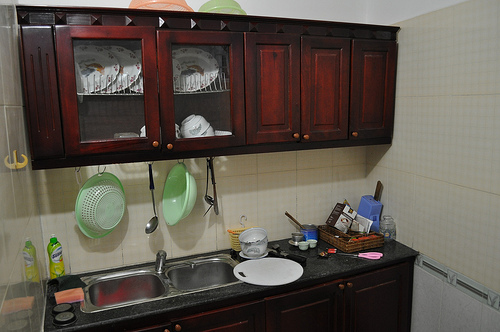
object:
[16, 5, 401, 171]
cabinets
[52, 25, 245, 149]
windows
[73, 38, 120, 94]
dishes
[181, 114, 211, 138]
cups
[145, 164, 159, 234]
ladle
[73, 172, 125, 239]
colanders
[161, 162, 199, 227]
utensils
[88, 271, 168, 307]
sinks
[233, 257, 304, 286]
plate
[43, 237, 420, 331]
counter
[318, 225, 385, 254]
tray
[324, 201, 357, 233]
items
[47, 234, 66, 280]
bottle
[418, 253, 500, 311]
tile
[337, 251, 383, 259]
scissors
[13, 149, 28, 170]
hook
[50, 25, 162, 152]
doors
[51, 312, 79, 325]
stopper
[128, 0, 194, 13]
bowl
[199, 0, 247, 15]
bowl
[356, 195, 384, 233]
block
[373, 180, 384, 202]
knife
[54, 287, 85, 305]
sponge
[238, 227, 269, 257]
bowl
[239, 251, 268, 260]
saucer